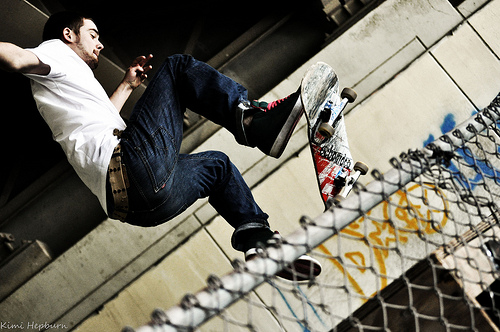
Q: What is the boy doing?
A: Riding a skateboard.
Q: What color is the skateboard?
A: Red, white and black.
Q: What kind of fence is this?
A: Chain link.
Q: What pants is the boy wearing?
A: Blue jeans.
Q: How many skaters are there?
A: One.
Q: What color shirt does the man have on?
A: White.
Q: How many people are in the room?
A: One.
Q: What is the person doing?
A: Skateboarding.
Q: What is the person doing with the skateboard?
A: Performing a stunt.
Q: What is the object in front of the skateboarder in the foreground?
A: Fence.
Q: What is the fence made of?
A: Metal.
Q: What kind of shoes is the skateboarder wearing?
A: Sneakers.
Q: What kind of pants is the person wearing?
A: Jeans.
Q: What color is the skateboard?
A: Red, white and black.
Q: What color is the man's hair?
A: Black.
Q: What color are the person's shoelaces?
A: Orange.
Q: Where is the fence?
A: Under skateboard.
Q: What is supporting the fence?
A: Metal pole.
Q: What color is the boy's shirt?
A: White.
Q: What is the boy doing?
A: Skating.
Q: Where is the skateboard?
A: Mid air.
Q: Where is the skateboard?
A: Under feet.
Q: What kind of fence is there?
A: Chain link.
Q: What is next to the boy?
A: Concrete structure.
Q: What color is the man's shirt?
A: White.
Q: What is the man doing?
A: Riding a skateboard.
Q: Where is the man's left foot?
A: Behind the skateboard.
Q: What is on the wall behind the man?
A: Graffiti.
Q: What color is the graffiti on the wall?
A: Yellow and Blue.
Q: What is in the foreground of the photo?
A: A chain-link fence.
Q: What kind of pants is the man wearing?
A: Jeans.